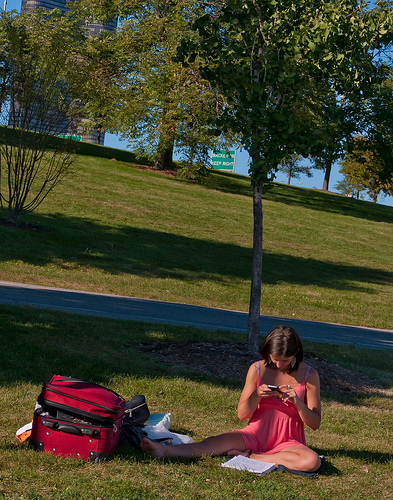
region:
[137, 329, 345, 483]
A woman sitting in the grass.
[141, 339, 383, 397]
Brown mulch around a tree.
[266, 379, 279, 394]
A cellphone.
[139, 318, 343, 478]
A woman looking down at a cell phone.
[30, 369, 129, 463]
A red and black luggage.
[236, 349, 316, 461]
A pink spaghetti strap dress.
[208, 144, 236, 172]
A green and white street sign.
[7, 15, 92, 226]
A bush with little leaves on it.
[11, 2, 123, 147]
A large building.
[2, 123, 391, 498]
A green grassy hill.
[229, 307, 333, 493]
lady looking at cellphone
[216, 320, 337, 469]
lady wearing a pink dress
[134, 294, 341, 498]
woman sitting on grass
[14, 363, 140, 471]
opened red luggage bag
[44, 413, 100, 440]
handle on red luggage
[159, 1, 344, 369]
tree behind lady on the grass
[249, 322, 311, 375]
woman with short hair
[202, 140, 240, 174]
green direction sign by road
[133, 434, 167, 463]
woman's bare right foot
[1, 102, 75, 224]
skinny brown bare tree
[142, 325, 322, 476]
Woman sitting on grass using smartphone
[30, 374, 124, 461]
Red bag sitting on ground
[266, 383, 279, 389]
Smartphone in woman's hand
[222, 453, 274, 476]
Open book laying in grass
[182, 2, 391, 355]
Tall tree in background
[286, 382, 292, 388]
Ring on woman's finger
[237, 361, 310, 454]
Pink spaghetti strap romper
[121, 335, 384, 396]
Mound of bark in grass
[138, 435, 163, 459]
Woman's bare foot without shoe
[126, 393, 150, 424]
Black zippered case sitting in grass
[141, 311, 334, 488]
Woman sitting on the grass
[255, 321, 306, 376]
Woman has brown hair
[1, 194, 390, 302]
Shadow on the grass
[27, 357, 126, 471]
The luggage is red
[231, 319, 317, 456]
Woman is wearing a pink dress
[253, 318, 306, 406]
Woman looking at cell phone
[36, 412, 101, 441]
Black handle on bag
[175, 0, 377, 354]
Tree behind the woman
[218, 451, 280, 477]
A white book on the grass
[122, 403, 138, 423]
Zipper on a bag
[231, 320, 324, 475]
woman wearing pink sundress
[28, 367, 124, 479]
red suitcase on grasss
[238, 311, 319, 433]
woman looking at cellphone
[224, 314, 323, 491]
book on grass in front of woman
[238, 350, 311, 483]
pink dress with white bra underneath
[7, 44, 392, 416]
tree with shade underneath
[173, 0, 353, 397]
tree with wood chips underneath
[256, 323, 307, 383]
woman with shoulder length hair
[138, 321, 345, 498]
woman with leg extended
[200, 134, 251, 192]
green street sign